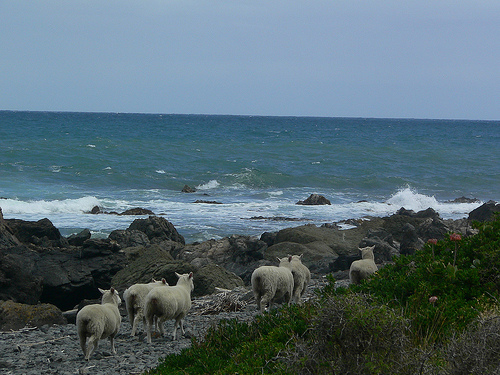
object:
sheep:
[76, 285, 123, 358]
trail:
[1, 320, 154, 372]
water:
[2, 130, 500, 200]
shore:
[3, 186, 500, 229]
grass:
[297, 302, 500, 373]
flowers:
[427, 233, 462, 268]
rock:
[297, 192, 330, 203]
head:
[97, 286, 122, 305]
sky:
[1, 1, 499, 78]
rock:
[0, 200, 499, 307]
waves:
[1, 184, 499, 219]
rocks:
[87, 184, 481, 221]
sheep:
[250, 254, 293, 314]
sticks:
[197, 295, 244, 314]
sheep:
[348, 243, 379, 286]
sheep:
[288, 252, 310, 297]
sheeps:
[75, 244, 377, 360]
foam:
[1, 178, 481, 220]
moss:
[4, 303, 58, 321]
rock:
[0, 300, 68, 331]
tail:
[84, 314, 94, 320]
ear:
[109, 286, 115, 296]